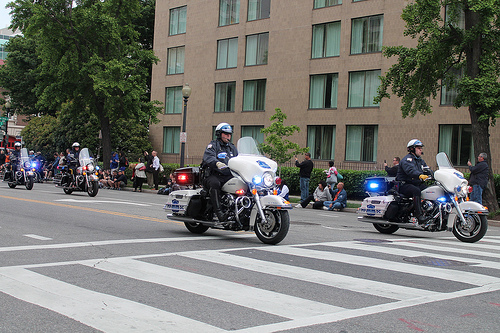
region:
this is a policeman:
[201, 120, 234, 179]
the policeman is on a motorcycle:
[165, 111, 290, 238]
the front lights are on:
[254, 170, 273, 186]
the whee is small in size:
[253, 210, 292, 240]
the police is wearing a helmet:
[214, 122, 229, 132]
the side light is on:
[366, 178, 379, 191]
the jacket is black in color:
[205, 146, 222, 167]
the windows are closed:
[315, 17, 380, 57]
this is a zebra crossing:
[130, 253, 450, 320]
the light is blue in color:
[368, 181, 380, 187]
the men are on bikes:
[10, 138, 487, 243]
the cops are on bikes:
[8, 140, 489, 243]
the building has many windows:
[143, 0, 497, 172]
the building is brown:
[141, 1, 490, 170]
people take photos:
[293, 152, 489, 203]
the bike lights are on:
[9, 142, 487, 238]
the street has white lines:
[0, 242, 497, 331]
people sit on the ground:
[311, 184, 350, 212]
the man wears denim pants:
[300, 177, 310, 198]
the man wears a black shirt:
[298, 161, 315, 175]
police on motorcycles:
[10, 123, 478, 240]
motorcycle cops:
[2, 131, 496, 253]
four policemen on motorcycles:
[6, 133, 495, 251]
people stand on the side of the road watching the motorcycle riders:
[6, 124, 498, 254]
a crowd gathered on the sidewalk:
[16, 140, 496, 210]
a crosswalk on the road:
[19, 226, 498, 329]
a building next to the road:
[149, 2, 497, 225]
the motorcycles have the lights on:
[20, 47, 488, 319]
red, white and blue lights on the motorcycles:
[12, 120, 491, 245]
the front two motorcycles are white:
[152, 128, 494, 250]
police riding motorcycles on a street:
[43, 121, 321, 261]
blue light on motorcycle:
[357, 171, 399, 202]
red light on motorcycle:
[155, 161, 207, 208]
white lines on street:
[33, 230, 458, 314]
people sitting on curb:
[277, 171, 358, 229]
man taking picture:
[287, 143, 314, 218]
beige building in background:
[123, 9, 411, 156]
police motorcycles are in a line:
[5, 126, 310, 258]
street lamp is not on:
[170, 71, 197, 171]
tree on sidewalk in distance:
[33, 12, 164, 150]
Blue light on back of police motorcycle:
[360, 172, 385, 193]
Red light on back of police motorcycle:
[166, 167, 196, 188]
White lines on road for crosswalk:
[61, 249, 381, 330]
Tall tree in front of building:
[407, 2, 492, 142]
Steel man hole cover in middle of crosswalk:
[407, 250, 474, 267]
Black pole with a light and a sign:
[176, 81, 196, 163]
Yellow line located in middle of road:
[49, 199, 114, 221]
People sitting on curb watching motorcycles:
[309, 176, 353, 212]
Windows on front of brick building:
[308, 20, 386, 136]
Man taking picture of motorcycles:
[291, 150, 318, 206]